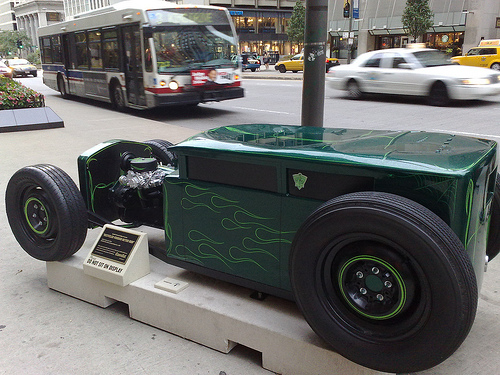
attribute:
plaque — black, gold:
[79, 222, 144, 284]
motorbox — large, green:
[3, 112, 488, 372]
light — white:
[166, 78, 180, 90]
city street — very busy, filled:
[7, 6, 498, 148]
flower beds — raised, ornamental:
[2, 71, 46, 108]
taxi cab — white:
[328, 41, 498, 103]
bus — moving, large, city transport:
[29, 8, 249, 113]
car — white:
[341, 36, 479, 131]